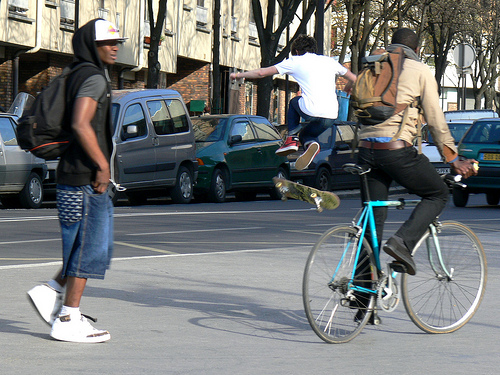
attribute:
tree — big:
[247, 0, 306, 114]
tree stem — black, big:
[144, 29, 160, 80]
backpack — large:
[324, 49, 446, 174]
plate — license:
[478, 150, 498, 162]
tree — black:
[432, 35, 443, 67]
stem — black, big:
[334, 14, 380, 84]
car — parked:
[0, 112, 49, 204]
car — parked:
[106, 88, 199, 201]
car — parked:
[193, 114, 287, 201]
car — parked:
[278, 122, 365, 193]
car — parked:
[423, 107, 496, 195]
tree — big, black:
[253, 1, 321, 112]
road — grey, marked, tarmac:
[2, 184, 495, 271]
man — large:
[16, 15, 130, 345]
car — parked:
[60, 76, 203, 199]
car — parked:
[178, 94, 296, 205]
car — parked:
[0, 90, 47, 209]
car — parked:
[284, 93, 372, 187]